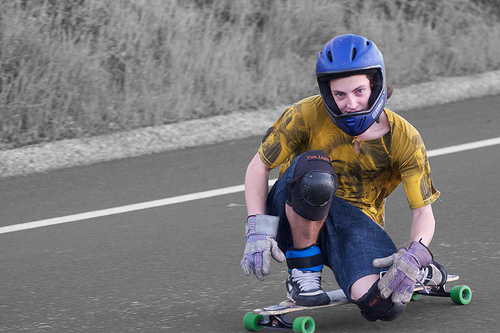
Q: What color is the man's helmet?
A: Blue.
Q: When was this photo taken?
A: During the day.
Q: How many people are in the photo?
A: One.